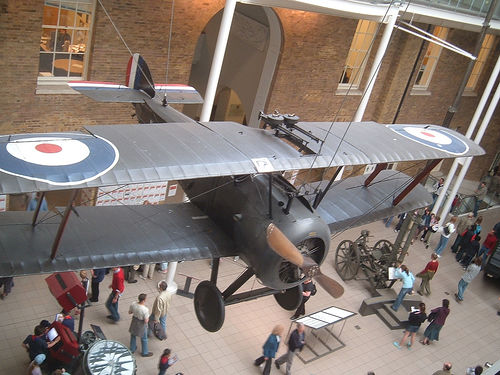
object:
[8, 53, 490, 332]
airplane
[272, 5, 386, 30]
ceiling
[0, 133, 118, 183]
blue cicles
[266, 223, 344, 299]
propellor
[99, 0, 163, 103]
wires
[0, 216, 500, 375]
floor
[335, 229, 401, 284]
cannon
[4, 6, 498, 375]
museum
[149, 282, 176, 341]
people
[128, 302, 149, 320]
tan shirts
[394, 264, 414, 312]
woman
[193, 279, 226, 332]
black wheels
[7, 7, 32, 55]
walls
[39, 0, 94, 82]
windows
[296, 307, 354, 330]
sign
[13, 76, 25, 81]
bricks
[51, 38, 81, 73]
office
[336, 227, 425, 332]
obstacle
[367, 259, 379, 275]
metal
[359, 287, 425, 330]
podium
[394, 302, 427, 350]
woman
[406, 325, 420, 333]
skirt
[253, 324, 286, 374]
woman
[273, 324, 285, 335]
blonde hair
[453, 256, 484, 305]
woman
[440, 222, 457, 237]
white shirt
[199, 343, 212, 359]
tile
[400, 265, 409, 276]
brown hair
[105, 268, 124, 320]
person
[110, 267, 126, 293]
red shirt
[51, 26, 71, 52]
person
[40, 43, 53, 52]
desk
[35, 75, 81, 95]
white trim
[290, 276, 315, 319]
person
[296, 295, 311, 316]
black pants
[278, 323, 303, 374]
person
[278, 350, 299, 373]
kakki pants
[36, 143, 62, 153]
dots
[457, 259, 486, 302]
person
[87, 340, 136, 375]
panels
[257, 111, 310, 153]
guns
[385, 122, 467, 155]
target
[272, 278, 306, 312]
wheels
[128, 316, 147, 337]
jacket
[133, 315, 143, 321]
waist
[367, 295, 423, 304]
platform